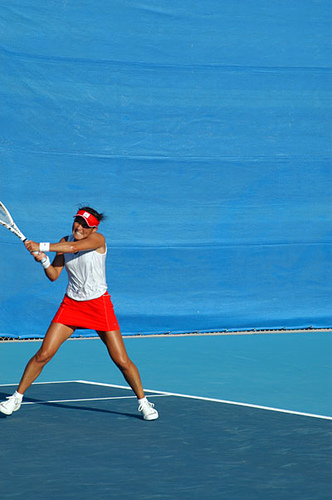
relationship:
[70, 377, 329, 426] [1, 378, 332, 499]
lines in bottom floor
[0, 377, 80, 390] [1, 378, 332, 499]
lines in bottom floor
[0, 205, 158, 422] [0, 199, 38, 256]
female swinging racket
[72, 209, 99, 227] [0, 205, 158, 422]
cap on female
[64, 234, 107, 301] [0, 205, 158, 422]
blouse on female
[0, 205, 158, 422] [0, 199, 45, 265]
female holding racket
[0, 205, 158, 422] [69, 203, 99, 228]
female wearing visor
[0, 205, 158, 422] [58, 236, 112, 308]
female wearing shirt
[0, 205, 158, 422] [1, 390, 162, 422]
female wearing sneakers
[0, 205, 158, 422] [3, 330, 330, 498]
female on tennis court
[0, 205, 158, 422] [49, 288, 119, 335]
female wearing female skirt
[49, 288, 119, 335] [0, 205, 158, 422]
female skirt on female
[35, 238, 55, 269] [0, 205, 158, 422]
armbands on female